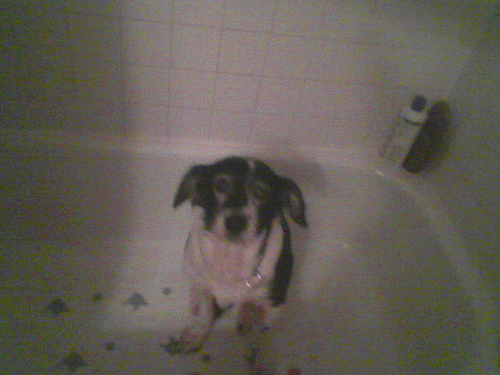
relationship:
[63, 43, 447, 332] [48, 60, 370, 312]
scene in bathroom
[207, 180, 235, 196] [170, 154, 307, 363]
eye on dog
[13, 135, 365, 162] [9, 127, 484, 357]
ledge of bathtub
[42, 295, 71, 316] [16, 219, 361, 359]
decals on the floor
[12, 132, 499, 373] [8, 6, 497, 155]
bathtub has wall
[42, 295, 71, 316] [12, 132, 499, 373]
decals on bathtub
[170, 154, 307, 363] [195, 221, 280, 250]
dog has collar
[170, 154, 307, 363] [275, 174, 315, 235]
dog has ear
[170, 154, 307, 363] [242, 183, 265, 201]
dog has eye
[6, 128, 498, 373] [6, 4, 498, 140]
bathroom has wall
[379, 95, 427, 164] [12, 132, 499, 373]
bottle on bathtub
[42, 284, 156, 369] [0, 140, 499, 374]
decals on bathtub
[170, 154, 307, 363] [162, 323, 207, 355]
dog has paw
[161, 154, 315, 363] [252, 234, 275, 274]
dog has collar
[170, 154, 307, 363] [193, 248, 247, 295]
dog has fur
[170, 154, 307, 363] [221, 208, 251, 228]
dog has snout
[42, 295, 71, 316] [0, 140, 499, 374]
decals on bathtub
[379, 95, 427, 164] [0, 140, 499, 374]
bottle on bathtub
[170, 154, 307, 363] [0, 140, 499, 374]
dog on bathtub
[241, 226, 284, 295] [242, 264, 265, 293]
collar has loop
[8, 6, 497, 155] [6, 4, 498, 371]
wall in bathroom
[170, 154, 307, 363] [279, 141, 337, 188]
dog has shadow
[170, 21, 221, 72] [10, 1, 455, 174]
tile attached to wall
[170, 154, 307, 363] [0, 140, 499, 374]
dog inside of bathtub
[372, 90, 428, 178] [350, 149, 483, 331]
bottle on ledge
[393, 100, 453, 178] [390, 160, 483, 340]
bottle on ledge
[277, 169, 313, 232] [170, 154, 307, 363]
ear of dog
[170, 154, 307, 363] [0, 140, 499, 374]
dog in bathtub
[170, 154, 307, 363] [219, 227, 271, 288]
dog has collar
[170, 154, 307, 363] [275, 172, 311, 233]
dog has ear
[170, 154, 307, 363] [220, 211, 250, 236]
dog has nose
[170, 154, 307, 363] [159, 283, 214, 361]
dog has leg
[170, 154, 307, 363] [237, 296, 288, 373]
dog has leg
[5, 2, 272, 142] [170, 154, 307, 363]
tile behind dog